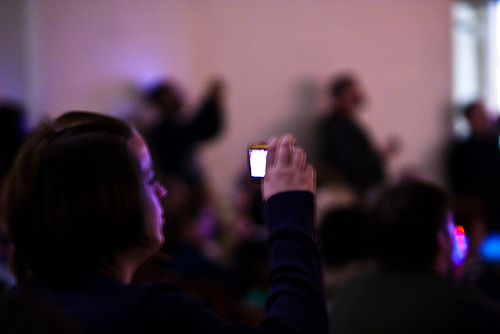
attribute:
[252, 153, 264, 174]
light — bright, white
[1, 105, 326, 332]
lady — standing, brunette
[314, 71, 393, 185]
person — standing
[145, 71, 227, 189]
another person — standing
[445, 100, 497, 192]
blurry person — standing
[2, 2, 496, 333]
picture — dark, blurry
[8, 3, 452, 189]
wall — white, beige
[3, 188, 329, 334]
sweater — blue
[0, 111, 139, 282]
hair — brown, short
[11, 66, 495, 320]
people — blurry, standing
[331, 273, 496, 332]
shirt — grey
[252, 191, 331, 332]
sleeve — long